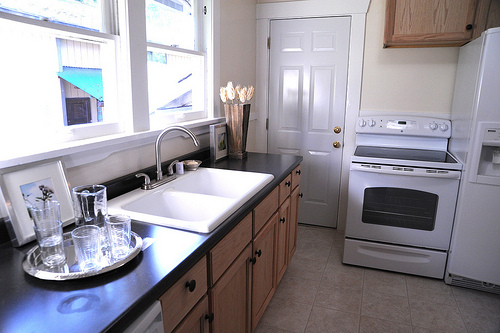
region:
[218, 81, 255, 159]
vase with stems of wheat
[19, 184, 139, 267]
water pitcher and drinking glasses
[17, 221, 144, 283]
silver serving tray with stemware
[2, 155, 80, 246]
framed photograph of plant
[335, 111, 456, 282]
new looking white glasstop oven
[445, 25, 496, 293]
new looking double-door fridge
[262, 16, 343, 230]
white door on wall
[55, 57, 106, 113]
green awning on building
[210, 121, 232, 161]
silver framed photograph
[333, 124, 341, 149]
brass door handle and dead bolt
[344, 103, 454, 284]
White stove with a smooth cooking surface.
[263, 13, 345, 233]
A Shiny white door.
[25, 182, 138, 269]
Clear glass drinking cups.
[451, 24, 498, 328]
White refrigerator with water dispenser.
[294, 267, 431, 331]
Brown tile floor covering.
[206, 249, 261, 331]
Brown cabinet with black knob.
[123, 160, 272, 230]
White double kitchen sink.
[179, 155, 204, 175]
A small silver soap dish.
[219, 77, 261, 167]
Vase with dried flowers.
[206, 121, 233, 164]
A picture in a frame.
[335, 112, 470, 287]
white stove with black top and oven door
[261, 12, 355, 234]
white door with gold door knob and lock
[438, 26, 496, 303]
white refrigerator with ice maker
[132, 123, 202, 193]
silver water faucet with two silver handles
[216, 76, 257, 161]
vase with light brown flowers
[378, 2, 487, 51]
brown cabinet on the wall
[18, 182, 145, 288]
silver tray with glasses of water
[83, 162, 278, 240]
double sink that is white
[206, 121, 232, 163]
small picture frame with silver border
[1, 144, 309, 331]
long countertop that is black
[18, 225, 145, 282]
silver tray with glasses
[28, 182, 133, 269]
drinking glasses on tray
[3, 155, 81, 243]
silver framed artwork on counter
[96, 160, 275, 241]
white porcelain kitchen sink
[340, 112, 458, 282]
white flat top stove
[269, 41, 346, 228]
closed white door reflecting sun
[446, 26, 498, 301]
portion of white refrigerator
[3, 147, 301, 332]
black topped kitchen counter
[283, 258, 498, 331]
brown tiled kitchen floor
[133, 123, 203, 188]
curved kitchen faucet on sink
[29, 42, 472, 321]
A kitchen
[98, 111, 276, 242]
A white kitchen sink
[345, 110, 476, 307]
A white oven in a kitchen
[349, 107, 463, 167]
white knobs on a stove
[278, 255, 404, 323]
A tile floor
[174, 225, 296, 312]
Wood cabinets in a kitchen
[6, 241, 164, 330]
A black kitchen counter top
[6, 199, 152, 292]
a tray on a counter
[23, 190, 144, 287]
glasses on a tray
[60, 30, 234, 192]
a window over a sink